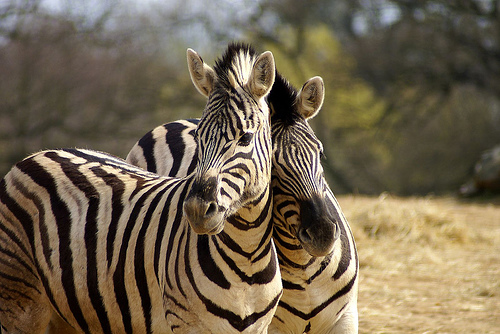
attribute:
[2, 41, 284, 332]
zebra — black, white, striped, standing, wild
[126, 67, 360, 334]
zebra — happy, black, whtie, striped, standing, white, cuddling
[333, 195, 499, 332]
field — brown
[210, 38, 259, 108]
mane — black, white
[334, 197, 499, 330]
grass — brown, dry, yellow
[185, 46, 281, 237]
head — striped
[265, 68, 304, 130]
mane — black